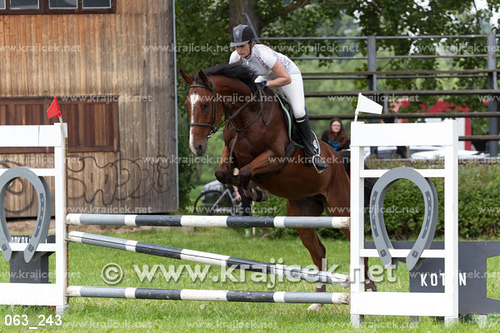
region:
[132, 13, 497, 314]
a man riding a horse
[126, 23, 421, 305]
a man on a brown hosre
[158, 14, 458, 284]
a man racing a horse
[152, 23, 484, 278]
a man racing a brown horse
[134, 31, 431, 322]
a horse jumping poles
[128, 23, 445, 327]
a brown horse jumping poles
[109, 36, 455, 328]
a horse that is jumping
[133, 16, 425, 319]
a brown horse that is jumping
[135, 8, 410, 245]
a racing horse that is jumping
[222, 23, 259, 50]
a black helmet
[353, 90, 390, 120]
a small white flag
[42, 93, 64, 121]
a small red flag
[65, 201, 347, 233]
a long black, white and gray pole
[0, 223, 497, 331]
a section of green grass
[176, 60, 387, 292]
a large brown horse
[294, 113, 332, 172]
a long black boot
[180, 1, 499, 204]
part of a large green tree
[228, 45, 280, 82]
part of a woman's white shirt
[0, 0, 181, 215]
part of a brown building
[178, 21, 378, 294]
Woman on a horse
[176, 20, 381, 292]
Woman making a horse jump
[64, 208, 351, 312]
Three white black and gray stiped poles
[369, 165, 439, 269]
Large gray horseshoe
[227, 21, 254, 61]
Black and gray horse riding helmet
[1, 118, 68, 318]
White fence with large horseshoe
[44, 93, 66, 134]
Small red flag on a white stick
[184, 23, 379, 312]
Woman competitively riding a horse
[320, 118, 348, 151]
Long haired woman in blue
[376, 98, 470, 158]
Red trailer with white door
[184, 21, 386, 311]
Woman on a brown horse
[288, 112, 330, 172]
Woman is wearing shoes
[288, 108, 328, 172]
Woman is wearing black shoes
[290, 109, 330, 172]
Woman is wearing boots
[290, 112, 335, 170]
Woman is wearing black boots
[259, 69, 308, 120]
Woman is wearing pants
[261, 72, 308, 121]
Woman is wearing white pants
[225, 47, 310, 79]
Woman is wearing a shirt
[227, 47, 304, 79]
Woman is wearing a white shirt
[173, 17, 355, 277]
person on a horse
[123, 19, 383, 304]
horse jumping over barrier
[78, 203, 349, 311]
barrier is black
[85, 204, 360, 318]
barrier is white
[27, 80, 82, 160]
barrier has a red flag on it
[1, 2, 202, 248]
building made of wood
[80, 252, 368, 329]
grass is green underneath the horse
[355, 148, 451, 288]
large black horseshoe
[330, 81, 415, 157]
flag is white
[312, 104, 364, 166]
woman in the background